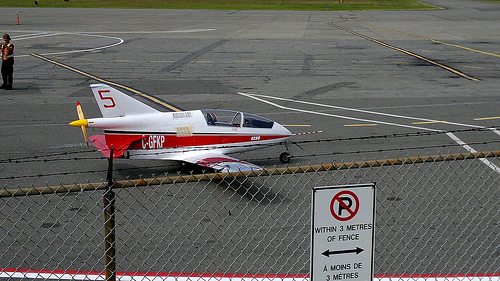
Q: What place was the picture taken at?
A: It was taken at the runway.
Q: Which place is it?
A: It is a runway.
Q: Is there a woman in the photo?
A: No, there are no women.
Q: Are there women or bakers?
A: No, there are no women or bakers.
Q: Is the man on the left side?
A: Yes, the man is on the left of the image.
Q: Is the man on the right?
A: No, the man is on the left of the image.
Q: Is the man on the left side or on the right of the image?
A: The man is on the left of the image.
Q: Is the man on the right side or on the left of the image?
A: The man is on the left of the image.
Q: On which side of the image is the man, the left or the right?
A: The man is on the left of the image.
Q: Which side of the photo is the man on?
A: The man is on the left of the image.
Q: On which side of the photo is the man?
A: The man is on the left of the image.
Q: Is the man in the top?
A: Yes, the man is in the top of the image.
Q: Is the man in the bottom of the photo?
A: No, the man is in the top of the image.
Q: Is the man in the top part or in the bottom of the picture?
A: The man is in the top of the image.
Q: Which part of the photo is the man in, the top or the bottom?
A: The man is in the top of the image.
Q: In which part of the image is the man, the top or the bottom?
A: The man is in the top of the image.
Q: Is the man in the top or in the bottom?
A: The man is in the top of the image.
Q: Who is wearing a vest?
A: The man is wearing a vest.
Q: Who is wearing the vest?
A: The man is wearing a vest.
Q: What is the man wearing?
A: The man is wearing a vest.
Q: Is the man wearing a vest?
A: Yes, the man is wearing a vest.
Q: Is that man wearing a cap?
A: No, the man is wearing a vest.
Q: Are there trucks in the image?
A: No, there are no trucks.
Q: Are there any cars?
A: No, there are no cars.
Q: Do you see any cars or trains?
A: No, there are no cars or trains.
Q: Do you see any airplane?
A: Yes, there is an airplane.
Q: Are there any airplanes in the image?
A: Yes, there is an airplane.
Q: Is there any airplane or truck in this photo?
A: Yes, there is an airplane.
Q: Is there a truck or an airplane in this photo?
A: Yes, there is an airplane.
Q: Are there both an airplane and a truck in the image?
A: No, there is an airplane but no trucks.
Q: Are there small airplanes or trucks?
A: Yes, there is a small airplane.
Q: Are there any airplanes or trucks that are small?
A: Yes, the airplane is small.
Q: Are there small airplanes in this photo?
A: Yes, there is a small airplane.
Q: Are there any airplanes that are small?
A: Yes, there is an airplane that is small.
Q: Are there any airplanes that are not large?
A: Yes, there is a small airplane.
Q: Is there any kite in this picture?
A: No, there are no kites.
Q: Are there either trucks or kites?
A: No, there are no kites or trucks.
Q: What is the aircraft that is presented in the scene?
A: The aircraft is an airplane.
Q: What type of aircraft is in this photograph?
A: The aircraft is an airplane.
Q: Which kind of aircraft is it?
A: The aircraft is an airplane.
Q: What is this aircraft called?
A: That is an airplane.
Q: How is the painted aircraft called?
A: The aircraft is an airplane.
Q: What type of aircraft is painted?
A: The aircraft is an airplane.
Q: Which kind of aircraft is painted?
A: The aircraft is an airplane.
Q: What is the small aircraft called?
A: The aircraft is an airplane.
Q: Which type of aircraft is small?
A: The aircraft is an airplane.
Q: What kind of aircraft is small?
A: The aircraft is an airplane.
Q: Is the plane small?
A: Yes, the plane is small.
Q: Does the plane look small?
A: Yes, the plane is small.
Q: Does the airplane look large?
A: No, the airplane is small.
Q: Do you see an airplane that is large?
A: No, there is an airplane but it is small.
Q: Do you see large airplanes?
A: No, there is an airplane but it is small.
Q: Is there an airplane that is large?
A: No, there is an airplane but it is small.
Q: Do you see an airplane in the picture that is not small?
A: No, there is an airplane but it is small.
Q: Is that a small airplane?
A: Yes, that is a small airplane.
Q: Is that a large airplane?
A: No, that is a small airplane.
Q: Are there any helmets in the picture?
A: No, there are no helmets.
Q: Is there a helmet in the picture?
A: No, there are no helmets.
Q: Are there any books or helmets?
A: No, there are no helmets or books.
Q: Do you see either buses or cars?
A: No, there are no cars or buses.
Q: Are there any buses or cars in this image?
A: No, there are no cars or buses.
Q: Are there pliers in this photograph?
A: No, there are no pliers.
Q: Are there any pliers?
A: No, there are no pliers.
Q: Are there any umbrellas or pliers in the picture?
A: No, there are no pliers or umbrellas.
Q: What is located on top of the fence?
A: The wire is on top of the fence.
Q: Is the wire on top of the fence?
A: Yes, the wire is on top of the fence.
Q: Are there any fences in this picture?
A: Yes, there is a fence.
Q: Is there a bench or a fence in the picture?
A: Yes, there is a fence.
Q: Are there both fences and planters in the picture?
A: No, there is a fence but no planters.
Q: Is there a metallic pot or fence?
A: Yes, there is a metal fence.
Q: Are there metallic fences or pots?
A: Yes, there is a metal fence.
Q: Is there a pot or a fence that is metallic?
A: Yes, the fence is metallic.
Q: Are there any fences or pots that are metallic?
A: Yes, the fence is metallic.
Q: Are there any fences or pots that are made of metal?
A: Yes, the fence is made of metal.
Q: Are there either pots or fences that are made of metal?
A: Yes, the fence is made of metal.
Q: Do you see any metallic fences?
A: Yes, there is a metal fence.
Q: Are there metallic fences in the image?
A: Yes, there is a metal fence.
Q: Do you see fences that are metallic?
A: Yes, there is a fence that is metallic.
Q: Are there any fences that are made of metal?
A: Yes, there is a fence that is made of metal.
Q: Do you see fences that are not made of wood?
A: Yes, there is a fence that is made of metal.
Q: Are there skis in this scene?
A: No, there are no skis.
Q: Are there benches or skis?
A: No, there are no skis or benches.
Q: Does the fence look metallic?
A: Yes, the fence is metallic.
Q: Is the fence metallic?
A: Yes, the fence is metallic.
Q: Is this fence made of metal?
A: Yes, the fence is made of metal.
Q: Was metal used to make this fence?
A: Yes, the fence is made of metal.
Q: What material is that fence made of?
A: The fence is made of metal.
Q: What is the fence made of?
A: The fence is made of metal.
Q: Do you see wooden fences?
A: No, there is a fence but it is metallic.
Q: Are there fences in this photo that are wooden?
A: No, there is a fence but it is metallic.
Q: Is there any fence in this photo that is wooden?
A: No, there is a fence but it is metallic.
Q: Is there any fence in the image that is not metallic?
A: No, there is a fence but it is metallic.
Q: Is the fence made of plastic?
A: No, the fence is made of metal.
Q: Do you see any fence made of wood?
A: No, there is a fence but it is made of metal.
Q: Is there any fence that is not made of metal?
A: No, there is a fence but it is made of metal.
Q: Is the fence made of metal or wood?
A: The fence is made of metal.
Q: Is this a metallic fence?
A: Yes, this is a metallic fence.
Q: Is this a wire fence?
A: No, this is a metallic fence.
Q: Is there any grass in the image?
A: Yes, there is grass.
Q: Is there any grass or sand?
A: Yes, there is grass.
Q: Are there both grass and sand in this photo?
A: No, there is grass but no sand.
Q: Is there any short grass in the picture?
A: Yes, there is short grass.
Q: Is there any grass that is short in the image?
A: Yes, there is short grass.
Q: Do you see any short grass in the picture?
A: Yes, there is short grass.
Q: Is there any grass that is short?
A: Yes, there is grass that is short.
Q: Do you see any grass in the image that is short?
A: Yes, there is grass that is short.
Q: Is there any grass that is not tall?
A: Yes, there is short grass.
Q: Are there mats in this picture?
A: No, there are no mats.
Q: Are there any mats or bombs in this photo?
A: No, there are no mats or bombs.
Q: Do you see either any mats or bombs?
A: No, there are no mats or bombs.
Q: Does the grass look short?
A: Yes, the grass is short.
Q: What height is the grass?
A: The grass is short.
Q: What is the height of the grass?
A: The grass is short.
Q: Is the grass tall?
A: No, the grass is short.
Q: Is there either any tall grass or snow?
A: No, there is grass but it is short.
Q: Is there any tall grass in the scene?
A: No, there is grass but it is short.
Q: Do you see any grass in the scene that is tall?
A: No, there is grass but it is short.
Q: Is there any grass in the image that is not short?
A: No, there is grass but it is short.